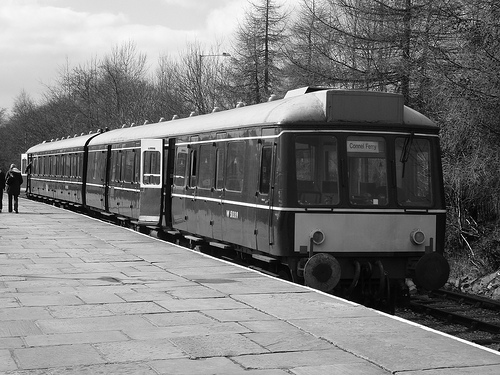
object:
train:
[12, 78, 460, 293]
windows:
[390, 128, 437, 213]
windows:
[341, 132, 393, 215]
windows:
[286, 129, 342, 210]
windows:
[255, 131, 280, 196]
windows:
[221, 135, 250, 199]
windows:
[212, 135, 228, 194]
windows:
[171, 132, 190, 190]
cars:
[85, 80, 451, 282]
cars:
[19, 124, 87, 215]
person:
[4, 159, 27, 216]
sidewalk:
[0, 186, 498, 374]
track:
[399, 273, 499, 336]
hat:
[10, 166, 23, 177]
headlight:
[406, 225, 431, 250]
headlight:
[310, 229, 328, 246]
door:
[137, 137, 166, 230]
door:
[17, 153, 31, 191]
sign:
[346, 136, 381, 155]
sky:
[1, 2, 499, 121]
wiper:
[398, 129, 414, 181]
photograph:
[0, 1, 498, 375]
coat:
[3, 167, 26, 199]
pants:
[7, 187, 21, 213]